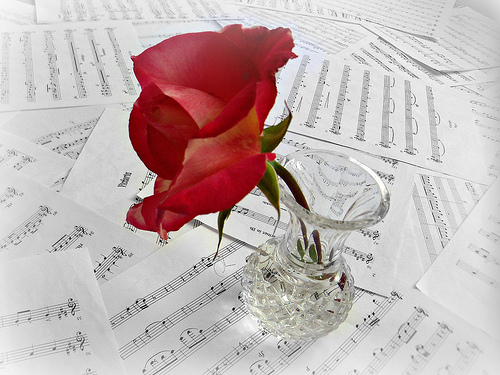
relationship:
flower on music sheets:
[122, 23, 392, 337] [10, 7, 479, 373]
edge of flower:
[227, 18, 295, 105] [104, 25, 356, 278]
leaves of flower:
[214, 98, 295, 260] [122, 21, 348, 302]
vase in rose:
[240, 143, 391, 345] [127, 23, 311, 241]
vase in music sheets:
[231, 131, 398, 361] [0, 1, 499, 373]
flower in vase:
[122, 23, 392, 337] [231, 137, 423, 354]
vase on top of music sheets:
[240, 143, 391, 345] [10, 7, 479, 373]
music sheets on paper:
[0, 1, 499, 373] [99, 222, 499, 374]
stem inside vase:
[255, 148, 341, 295] [240, 143, 391, 345]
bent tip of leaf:
[283, 99, 291, 115] [261, 100, 292, 152]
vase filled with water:
[240, 143, 391, 345] [241, 232, 354, 339]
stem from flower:
[255, 148, 341, 295] [124, 37, 340, 253]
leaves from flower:
[214, 208, 226, 260] [124, 37, 340, 253]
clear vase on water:
[242, 145, 383, 347] [267, 256, 334, 314]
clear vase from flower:
[242, 145, 383, 347] [124, 20, 297, 241]